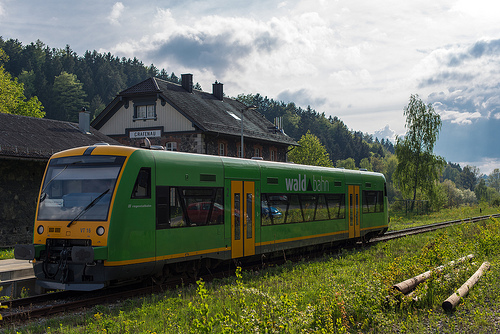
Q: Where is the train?
A: Train tracks.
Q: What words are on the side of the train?
A: Wald bahn.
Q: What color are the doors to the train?
A: Yellow.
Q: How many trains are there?
A: One.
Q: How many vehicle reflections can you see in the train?
A: Two.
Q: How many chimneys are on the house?
A: Two.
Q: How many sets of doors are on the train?
A: Two.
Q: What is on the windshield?
A: Windshield wiper.